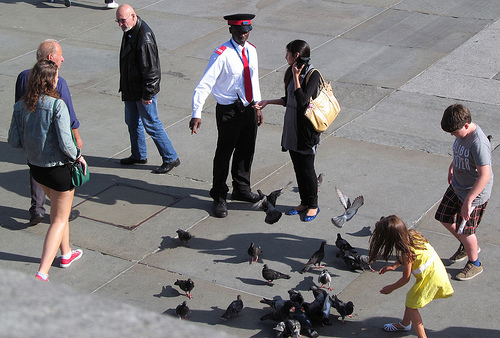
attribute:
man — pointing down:
[183, 8, 270, 223]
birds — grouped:
[160, 181, 377, 337]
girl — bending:
[362, 206, 460, 337]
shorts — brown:
[427, 98, 496, 283]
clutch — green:
[68, 161, 92, 186]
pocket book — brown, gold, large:
[302, 68, 343, 138]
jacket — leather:
[111, 25, 168, 99]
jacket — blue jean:
[3, 93, 82, 170]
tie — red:
[237, 47, 257, 106]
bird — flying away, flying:
[326, 181, 366, 231]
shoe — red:
[57, 246, 84, 269]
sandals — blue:
[283, 202, 323, 222]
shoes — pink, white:
[38, 246, 84, 281]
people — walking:
[5, 2, 185, 290]